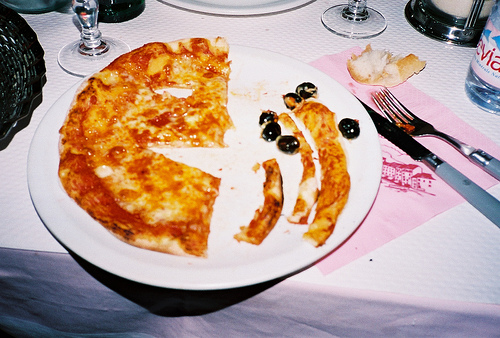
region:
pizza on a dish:
[0, 35, 429, 301]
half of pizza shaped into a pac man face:
[81, 20, 233, 265]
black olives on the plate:
[247, 77, 366, 149]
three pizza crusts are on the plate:
[241, 107, 344, 252]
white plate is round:
[26, 34, 383, 302]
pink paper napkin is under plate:
[313, 151, 465, 281]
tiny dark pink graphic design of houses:
[375, 147, 435, 213]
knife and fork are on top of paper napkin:
[370, 72, 472, 247]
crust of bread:
[338, 40, 424, 97]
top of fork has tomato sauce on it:
[363, 82, 440, 143]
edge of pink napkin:
[362, 222, 446, 270]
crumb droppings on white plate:
[239, 152, 271, 174]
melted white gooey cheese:
[303, 181, 327, 198]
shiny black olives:
[257, 124, 304, 161]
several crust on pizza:
[117, 93, 199, 147]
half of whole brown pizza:
[71, 39, 258, 237]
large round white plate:
[34, 37, 434, 270]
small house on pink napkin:
[362, 145, 449, 205]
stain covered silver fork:
[368, 81, 456, 163]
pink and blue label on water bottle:
[461, 32, 496, 87]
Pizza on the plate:
[58, 33, 231, 256]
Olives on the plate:
[258, 82, 360, 153]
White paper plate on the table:
[26, 42, 381, 287]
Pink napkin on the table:
[298, 45, 499, 273]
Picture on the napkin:
[385, 142, 437, 197]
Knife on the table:
[353, 92, 498, 220]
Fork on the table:
[371, 83, 498, 180]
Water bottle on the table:
[464, 6, 498, 107]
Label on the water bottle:
[471, 19, 499, 86]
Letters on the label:
[475, 38, 499, 70]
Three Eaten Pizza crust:
[290, 100, 345, 235]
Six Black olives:
[255, 75, 350, 145]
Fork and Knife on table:
[345, 95, 490, 240]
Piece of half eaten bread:
[335, 35, 430, 80]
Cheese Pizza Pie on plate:
[120, 80, 285, 230]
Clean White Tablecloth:
[415, 235, 490, 300]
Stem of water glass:
[55, 0, 125, 70]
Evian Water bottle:
[465, 5, 490, 60]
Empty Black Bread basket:
[0, 5, 50, 145]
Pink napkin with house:
[375, 175, 451, 230]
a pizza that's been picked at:
[57, 36, 361, 256]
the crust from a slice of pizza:
[232, 158, 285, 248]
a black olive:
[276, 132, 299, 156]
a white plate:
[224, 37, 246, 272]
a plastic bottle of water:
[466, 5, 498, 116]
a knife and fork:
[371, 84, 498, 237]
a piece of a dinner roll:
[344, 42, 424, 88]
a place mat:
[383, 155, 429, 227]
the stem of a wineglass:
[66, 1, 127, 69]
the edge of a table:
[6, 241, 59, 269]